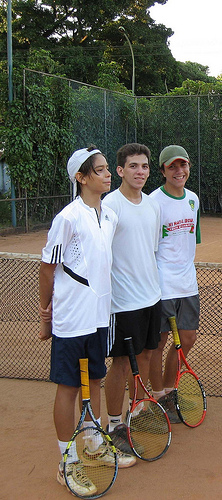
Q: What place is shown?
A: It is a forest.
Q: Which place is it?
A: It is a forest.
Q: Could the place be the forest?
A: Yes, it is the forest.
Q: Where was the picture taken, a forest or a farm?
A: It was taken at a forest.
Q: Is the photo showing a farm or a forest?
A: It is showing a forest.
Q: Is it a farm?
A: No, it is a forest.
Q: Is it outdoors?
A: Yes, it is outdoors.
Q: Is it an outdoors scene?
A: Yes, it is outdoors.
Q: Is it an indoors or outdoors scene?
A: It is outdoors.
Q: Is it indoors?
A: No, it is outdoors.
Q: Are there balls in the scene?
A: No, there are no balls.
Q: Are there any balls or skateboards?
A: No, there are no balls or skateboards.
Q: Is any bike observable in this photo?
A: No, there are no bikes.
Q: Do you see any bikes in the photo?
A: No, there are no bikes.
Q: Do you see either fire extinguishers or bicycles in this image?
A: No, there are no bicycles or fire extinguishers.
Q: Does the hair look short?
A: Yes, the hair is short.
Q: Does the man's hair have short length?
A: Yes, the hair is short.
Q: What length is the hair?
A: The hair is short.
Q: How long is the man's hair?
A: The hair is short.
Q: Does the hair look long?
A: No, the hair is short.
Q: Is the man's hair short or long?
A: The hair is short.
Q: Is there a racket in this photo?
A: Yes, there is a racket.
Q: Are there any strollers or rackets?
A: Yes, there is a racket.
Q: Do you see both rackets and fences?
A: Yes, there are both a racket and a fence.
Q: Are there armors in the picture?
A: No, there are no armors.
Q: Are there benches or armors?
A: No, there are no armors or benches.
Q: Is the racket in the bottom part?
A: Yes, the racket is in the bottom of the image.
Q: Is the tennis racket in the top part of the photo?
A: No, the tennis racket is in the bottom of the image.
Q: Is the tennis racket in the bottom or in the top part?
A: The tennis racket is in the bottom of the image.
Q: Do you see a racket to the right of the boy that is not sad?
A: Yes, there is a racket to the right of the boy.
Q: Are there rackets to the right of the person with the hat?
A: Yes, there is a racket to the right of the boy.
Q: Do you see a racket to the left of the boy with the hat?
A: No, the racket is to the right of the boy.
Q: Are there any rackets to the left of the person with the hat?
A: No, the racket is to the right of the boy.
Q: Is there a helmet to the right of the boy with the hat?
A: No, there is a racket to the right of the boy.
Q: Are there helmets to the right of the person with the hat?
A: No, there is a racket to the right of the boy.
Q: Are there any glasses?
A: No, there are no glasses.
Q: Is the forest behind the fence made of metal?
A: Yes, the forest is behind the fence.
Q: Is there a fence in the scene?
A: Yes, there is a fence.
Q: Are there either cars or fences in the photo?
A: Yes, there is a fence.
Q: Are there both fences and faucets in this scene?
A: No, there is a fence but no faucets.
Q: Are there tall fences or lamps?
A: Yes, there is a tall fence.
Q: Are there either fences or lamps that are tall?
A: Yes, the fence is tall.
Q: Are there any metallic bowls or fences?
A: Yes, there is a metal fence.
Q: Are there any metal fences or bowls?
A: Yes, there is a metal fence.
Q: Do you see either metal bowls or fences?
A: Yes, there is a metal fence.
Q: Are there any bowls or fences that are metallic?
A: Yes, the fence is metallic.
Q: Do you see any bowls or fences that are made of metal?
A: Yes, the fence is made of metal.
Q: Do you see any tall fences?
A: Yes, there is a tall fence.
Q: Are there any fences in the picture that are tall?
A: Yes, there is a fence that is tall.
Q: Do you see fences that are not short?
A: Yes, there is a tall fence.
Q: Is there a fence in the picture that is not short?
A: Yes, there is a tall fence.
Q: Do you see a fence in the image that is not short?
A: Yes, there is a tall fence.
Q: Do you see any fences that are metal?
A: Yes, there is a metal fence.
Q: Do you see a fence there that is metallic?
A: Yes, there is a fence that is metallic.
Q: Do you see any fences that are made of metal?
A: Yes, there is a fence that is made of metal.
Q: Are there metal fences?
A: Yes, there is a fence that is made of metal.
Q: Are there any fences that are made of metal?
A: Yes, there is a fence that is made of metal.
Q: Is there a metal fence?
A: Yes, there is a fence that is made of metal.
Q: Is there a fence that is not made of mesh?
A: Yes, there is a fence that is made of metal.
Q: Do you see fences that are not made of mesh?
A: Yes, there is a fence that is made of metal.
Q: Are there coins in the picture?
A: No, there are no coins.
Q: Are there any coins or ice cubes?
A: No, there are no coins or ice cubes.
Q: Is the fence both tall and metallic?
A: Yes, the fence is tall and metallic.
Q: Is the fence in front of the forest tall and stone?
A: No, the fence is tall but metallic.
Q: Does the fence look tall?
A: Yes, the fence is tall.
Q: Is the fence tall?
A: Yes, the fence is tall.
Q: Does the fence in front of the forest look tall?
A: Yes, the fence is tall.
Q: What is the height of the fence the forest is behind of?
A: The fence is tall.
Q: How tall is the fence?
A: The fence is tall.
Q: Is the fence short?
A: No, the fence is tall.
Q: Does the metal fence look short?
A: No, the fence is tall.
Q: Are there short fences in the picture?
A: No, there is a fence but it is tall.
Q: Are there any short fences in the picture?
A: No, there is a fence but it is tall.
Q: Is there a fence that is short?
A: No, there is a fence but it is tall.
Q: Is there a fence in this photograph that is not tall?
A: No, there is a fence but it is tall.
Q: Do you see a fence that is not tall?
A: No, there is a fence but it is tall.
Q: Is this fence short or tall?
A: The fence is tall.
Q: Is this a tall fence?
A: Yes, this is a tall fence.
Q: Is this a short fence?
A: No, this is a tall fence.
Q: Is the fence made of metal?
A: Yes, the fence is made of metal.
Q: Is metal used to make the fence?
A: Yes, the fence is made of metal.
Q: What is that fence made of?
A: The fence is made of metal.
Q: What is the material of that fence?
A: The fence is made of metal.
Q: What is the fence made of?
A: The fence is made of metal.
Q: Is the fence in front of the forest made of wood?
A: No, the fence is made of metal.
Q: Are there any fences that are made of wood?
A: No, there is a fence but it is made of metal.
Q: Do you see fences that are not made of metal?
A: No, there is a fence but it is made of metal.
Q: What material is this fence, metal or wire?
A: The fence is made of metal.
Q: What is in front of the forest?
A: The fence is in front of the forest.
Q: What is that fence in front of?
A: The fence is in front of the forest.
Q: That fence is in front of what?
A: The fence is in front of the forest.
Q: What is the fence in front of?
A: The fence is in front of the forest.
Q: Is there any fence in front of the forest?
A: Yes, there is a fence in front of the forest.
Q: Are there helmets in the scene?
A: No, there are no helmets.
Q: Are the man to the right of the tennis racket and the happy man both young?
A: Yes, both the man and the man are young.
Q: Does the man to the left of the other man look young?
A: Yes, the man is young.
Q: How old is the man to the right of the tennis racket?
A: The man is young.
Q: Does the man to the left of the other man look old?
A: No, the man is young.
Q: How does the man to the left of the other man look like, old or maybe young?
A: The man is young.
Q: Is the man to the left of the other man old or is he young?
A: The man is young.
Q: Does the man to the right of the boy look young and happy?
A: Yes, the man is young and happy.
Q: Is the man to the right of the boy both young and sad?
A: No, the man is young but happy.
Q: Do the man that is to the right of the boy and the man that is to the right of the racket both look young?
A: Yes, both the man and the man are young.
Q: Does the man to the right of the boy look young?
A: Yes, the man is young.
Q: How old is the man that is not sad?
A: The man is young.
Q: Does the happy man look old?
A: No, the man is young.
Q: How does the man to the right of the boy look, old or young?
A: The man is young.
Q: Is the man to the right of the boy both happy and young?
A: Yes, the man is happy and young.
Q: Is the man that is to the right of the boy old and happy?
A: No, the man is happy but young.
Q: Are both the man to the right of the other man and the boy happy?
A: Yes, both the man and the boy are happy.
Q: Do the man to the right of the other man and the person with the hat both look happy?
A: Yes, both the man and the boy are happy.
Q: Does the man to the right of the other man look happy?
A: Yes, the man is happy.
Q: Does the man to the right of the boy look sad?
A: No, the man is happy.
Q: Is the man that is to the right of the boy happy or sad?
A: The man is happy.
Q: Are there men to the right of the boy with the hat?
A: Yes, there is a man to the right of the boy.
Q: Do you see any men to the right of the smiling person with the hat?
A: Yes, there is a man to the right of the boy.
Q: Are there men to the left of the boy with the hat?
A: No, the man is to the right of the boy.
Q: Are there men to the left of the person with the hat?
A: No, the man is to the right of the boy.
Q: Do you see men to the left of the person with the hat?
A: No, the man is to the right of the boy.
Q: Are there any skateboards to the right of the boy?
A: No, there is a man to the right of the boy.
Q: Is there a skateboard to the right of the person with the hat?
A: No, there is a man to the right of the boy.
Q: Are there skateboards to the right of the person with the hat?
A: No, there is a man to the right of the boy.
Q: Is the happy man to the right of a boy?
A: Yes, the man is to the right of a boy.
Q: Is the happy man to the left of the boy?
A: No, the man is to the right of the boy.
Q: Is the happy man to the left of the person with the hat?
A: No, the man is to the right of the boy.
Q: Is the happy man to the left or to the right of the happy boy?
A: The man is to the right of the boy.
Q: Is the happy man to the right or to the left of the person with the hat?
A: The man is to the right of the boy.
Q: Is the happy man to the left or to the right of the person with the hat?
A: The man is to the right of the boy.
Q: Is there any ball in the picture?
A: No, there are no balls.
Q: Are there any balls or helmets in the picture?
A: No, there are no balls or helmets.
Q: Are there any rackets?
A: Yes, there is a racket.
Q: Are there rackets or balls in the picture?
A: Yes, there is a racket.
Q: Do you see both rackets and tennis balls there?
A: No, there is a racket but no tennis balls.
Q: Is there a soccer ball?
A: No, there are no soccer balls.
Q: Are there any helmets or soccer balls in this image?
A: No, there are no soccer balls or helmets.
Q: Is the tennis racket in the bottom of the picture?
A: Yes, the tennis racket is in the bottom of the image.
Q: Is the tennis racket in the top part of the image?
A: No, the tennis racket is in the bottom of the image.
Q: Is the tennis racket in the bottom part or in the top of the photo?
A: The tennis racket is in the bottom of the image.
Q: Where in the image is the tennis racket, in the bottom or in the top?
A: The tennis racket is in the bottom of the image.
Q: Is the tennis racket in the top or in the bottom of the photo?
A: The tennis racket is in the bottom of the image.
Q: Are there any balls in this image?
A: No, there are no balls.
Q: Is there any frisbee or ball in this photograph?
A: No, there are no balls or frisbees.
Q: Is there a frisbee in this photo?
A: No, there are no frisbees.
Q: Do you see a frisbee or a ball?
A: No, there are no frisbees or balls.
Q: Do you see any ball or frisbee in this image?
A: No, there are no frisbees or balls.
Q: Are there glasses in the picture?
A: No, there are no glasses.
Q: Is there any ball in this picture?
A: No, there are no balls.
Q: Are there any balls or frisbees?
A: No, there are no balls or frisbees.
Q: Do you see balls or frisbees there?
A: No, there are no balls or frisbees.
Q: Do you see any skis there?
A: No, there are no skis.